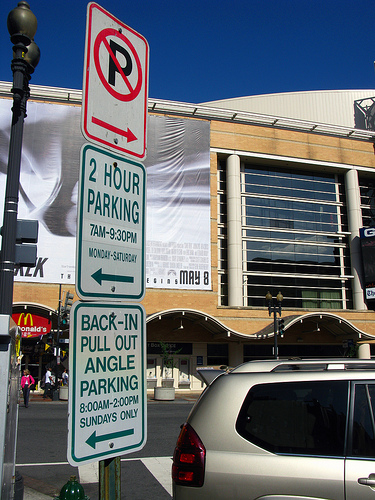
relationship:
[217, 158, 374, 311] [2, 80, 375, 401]
windows on building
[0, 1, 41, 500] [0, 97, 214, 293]
lamppost in front of banner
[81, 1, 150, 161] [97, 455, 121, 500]
sign on a post